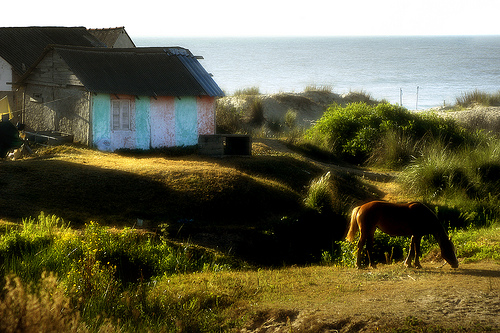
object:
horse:
[346, 201, 458, 270]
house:
[14, 45, 226, 153]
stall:
[198, 134, 252, 159]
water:
[127, 34, 500, 110]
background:
[0, 0, 499, 219]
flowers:
[57, 221, 127, 310]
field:
[0, 90, 500, 331]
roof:
[14, 47, 226, 97]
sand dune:
[215, 80, 500, 143]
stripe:
[150, 96, 176, 150]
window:
[110, 99, 132, 130]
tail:
[346, 206, 361, 242]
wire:
[0, 95, 73, 116]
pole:
[415, 85, 419, 109]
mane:
[422, 204, 448, 240]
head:
[440, 240, 459, 268]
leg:
[355, 227, 375, 269]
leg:
[366, 226, 377, 269]